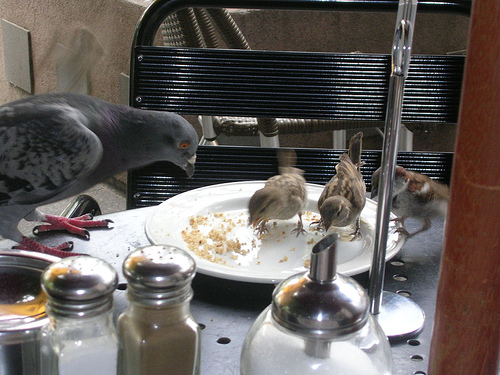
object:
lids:
[121, 244, 197, 310]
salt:
[40, 324, 118, 375]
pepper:
[115, 307, 199, 374]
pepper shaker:
[115, 244, 201, 375]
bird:
[0, 92, 199, 259]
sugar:
[246, 322, 382, 374]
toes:
[11, 236, 90, 257]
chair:
[126, 0, 472, 211]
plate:
[144, 180, 409, 284]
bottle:
[36, 255, 122, 375]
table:
[0, 171, 451, 375]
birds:
[310, 131, 367, 241]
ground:
[333, 91, 390, 170]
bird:
[370, 163, 452, 239]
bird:
[247, 149, 307, 238]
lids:
[39, 255, 119, 320]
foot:
[24, 208, 114, 239]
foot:
[6, 228, 91, 257]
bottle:
[240, 270, 394, 375]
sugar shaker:
[239, 232, 394, 375]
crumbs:
[181, 210, 367, 268]